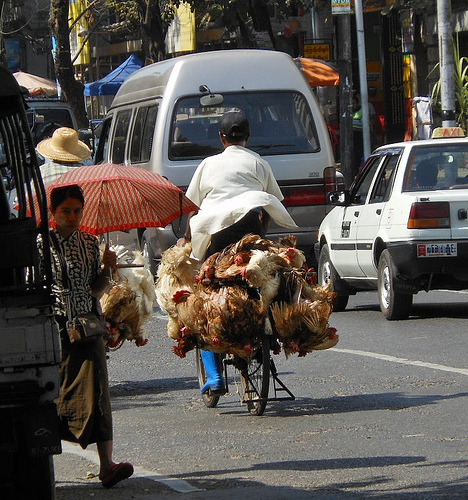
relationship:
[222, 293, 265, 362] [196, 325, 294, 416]
chicken hanging on bike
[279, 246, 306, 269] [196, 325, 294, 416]
chicken hanging on bike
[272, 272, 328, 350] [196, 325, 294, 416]
chicken hanging on bike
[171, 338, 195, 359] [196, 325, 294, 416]
chicken hanging on bike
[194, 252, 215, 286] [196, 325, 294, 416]
chicken hanging on bike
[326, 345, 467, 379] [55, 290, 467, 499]
line painted on road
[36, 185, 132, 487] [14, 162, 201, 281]
woman has umbrella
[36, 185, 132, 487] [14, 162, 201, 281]
woman holding umbrella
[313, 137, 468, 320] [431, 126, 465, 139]
car has taxi sign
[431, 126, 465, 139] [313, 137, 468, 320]
taxi sign on top of car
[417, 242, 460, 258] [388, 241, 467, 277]
sticker attached to bumper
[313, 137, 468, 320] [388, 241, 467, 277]
car has bumper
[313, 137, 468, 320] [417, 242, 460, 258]
car has sticker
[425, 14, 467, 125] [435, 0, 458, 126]
plant behind pole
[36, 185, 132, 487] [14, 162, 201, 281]
woman carrying umbrella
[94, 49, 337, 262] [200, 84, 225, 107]
van has mirror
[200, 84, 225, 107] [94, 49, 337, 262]
mirror attached to back of van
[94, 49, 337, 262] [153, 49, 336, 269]
van has back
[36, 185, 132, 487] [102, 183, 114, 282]
woman holding handle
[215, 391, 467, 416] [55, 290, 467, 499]
shadow cast on road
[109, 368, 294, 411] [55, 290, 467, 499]
shadow cast on road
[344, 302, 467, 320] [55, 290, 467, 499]
shadow cast on road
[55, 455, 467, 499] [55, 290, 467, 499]
shadow cast on road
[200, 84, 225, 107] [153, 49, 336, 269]
mirror attached to back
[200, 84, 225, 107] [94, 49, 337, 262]
mirror attached to van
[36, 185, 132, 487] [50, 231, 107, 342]
woman has purse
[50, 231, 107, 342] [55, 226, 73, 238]
purse around neck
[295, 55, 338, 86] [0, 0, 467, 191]
umbrella on sidewalk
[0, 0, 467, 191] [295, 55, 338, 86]
sidewalk has umbrella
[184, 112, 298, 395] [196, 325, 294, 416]
man riding bike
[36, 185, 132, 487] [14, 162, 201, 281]
woman walking with umbrella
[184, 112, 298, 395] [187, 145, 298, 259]
man wearing shirt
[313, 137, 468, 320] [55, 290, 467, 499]
car on top of road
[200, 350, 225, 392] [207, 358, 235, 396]
boot on top of pedal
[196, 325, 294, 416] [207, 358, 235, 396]
bike has pedal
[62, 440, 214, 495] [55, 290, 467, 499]
line painted on road